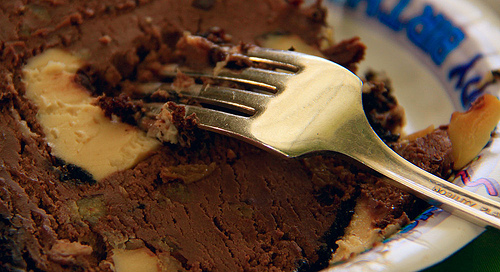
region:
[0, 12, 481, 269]
icecream in bowl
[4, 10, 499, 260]
ice cream on a paper bowl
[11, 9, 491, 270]
a fork in the ice cream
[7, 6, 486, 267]
a silver fork in the ice cream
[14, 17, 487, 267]
chocolate ice cream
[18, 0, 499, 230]
eating ice cream with a fork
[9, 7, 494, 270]
a bowl of ice cream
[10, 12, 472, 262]
a bowl with ice cream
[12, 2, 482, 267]
a bowl of chocolate ice cream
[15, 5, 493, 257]
a paper bowl with ice cream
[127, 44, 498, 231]
Silver fork with four tines on the end.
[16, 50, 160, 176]
Large tan spot to the left of the fork.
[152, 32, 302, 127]
Four silver tines on the bottom of a fork.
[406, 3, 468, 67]
Electric blue BIR on the side of a white plate.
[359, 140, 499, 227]
Silver handle on a fork.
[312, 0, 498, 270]
White paper plate with blue writing on the edge.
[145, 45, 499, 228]
Silver fork sticking out of a dessert.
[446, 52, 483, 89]
A dark Y on the edge of a plate.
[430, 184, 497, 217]
Small unreadble writing on the back of a silver fork handle.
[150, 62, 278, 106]
Two middle silver tines of a fork.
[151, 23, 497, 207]
silver steel fork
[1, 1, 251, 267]
chocolate frosted cake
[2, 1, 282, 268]
chocolate frosting with vanilla inside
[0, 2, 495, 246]
cake on paper plate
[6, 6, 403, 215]
fork in to cake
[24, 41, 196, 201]
vanilla inside cake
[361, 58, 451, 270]
silver handle on fork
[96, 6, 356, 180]
fork with cake on it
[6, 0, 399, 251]
partial eaten cake on plate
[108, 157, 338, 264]
brown colored frosting on cake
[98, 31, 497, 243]
piece of cake on fork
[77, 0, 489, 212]
upside down fork with chocolate cake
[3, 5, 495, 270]
chocolate cake in a birthday paper bowl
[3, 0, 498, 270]
chocolate cheese cake in bowl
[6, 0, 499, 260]
white and blue lettering on paper bowl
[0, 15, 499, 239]
paper bowl has fork with chocolate cake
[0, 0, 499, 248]
chocolate cheese cake has an inverted fork in it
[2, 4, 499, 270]
blue and white paper bowl has chocolate chese cake in it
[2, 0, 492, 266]
fork is on top of chocolate cheese cake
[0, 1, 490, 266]
birthday bowl has a fork and chocolate cheese cake on it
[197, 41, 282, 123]
The sporks of the fork.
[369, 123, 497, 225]
The handle of the fork.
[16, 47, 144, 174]
The light colored part of the cake.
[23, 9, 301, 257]
The chocolate part of the cake.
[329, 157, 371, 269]
The dark chocolate of the cake.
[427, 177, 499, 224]
The engraving on the fork's handle.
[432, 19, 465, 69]
The letter B on the plate.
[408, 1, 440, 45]
The letter R on the plate.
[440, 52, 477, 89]
The Y on the plate.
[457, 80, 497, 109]
The letter P on the plate.